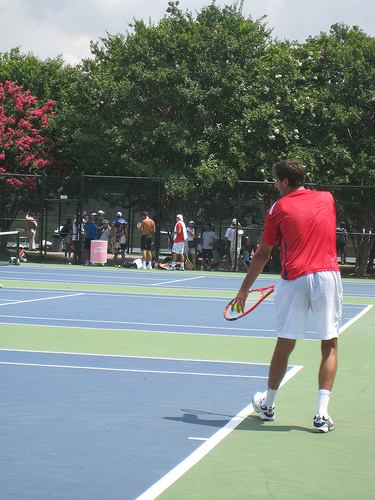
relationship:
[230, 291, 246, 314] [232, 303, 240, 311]
hand holding ball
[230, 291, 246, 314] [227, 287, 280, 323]
hand holding racket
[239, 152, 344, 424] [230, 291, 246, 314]
player has hand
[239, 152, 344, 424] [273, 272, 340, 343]
player has shorts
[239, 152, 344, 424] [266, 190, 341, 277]
player has shirt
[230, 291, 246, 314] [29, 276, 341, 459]
hand facing ground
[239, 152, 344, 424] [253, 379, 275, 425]
player has foot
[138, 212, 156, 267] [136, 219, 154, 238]
man has torso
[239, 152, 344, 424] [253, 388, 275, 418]
player has shoe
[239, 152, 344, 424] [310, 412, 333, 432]
player has shoe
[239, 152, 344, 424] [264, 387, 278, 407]
player has sock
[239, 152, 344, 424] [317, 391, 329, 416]
player has sock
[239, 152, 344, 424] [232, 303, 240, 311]
player has ball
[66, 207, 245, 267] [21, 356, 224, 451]
spectators near court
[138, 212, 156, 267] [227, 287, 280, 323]
man holding racket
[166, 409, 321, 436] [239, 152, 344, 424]
shadow of player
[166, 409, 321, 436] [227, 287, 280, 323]
shadow of racket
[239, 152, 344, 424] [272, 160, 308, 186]
player has hair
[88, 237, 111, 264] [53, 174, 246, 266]
barrel near fence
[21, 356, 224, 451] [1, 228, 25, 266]
court has net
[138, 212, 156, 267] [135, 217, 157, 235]
man bare chested